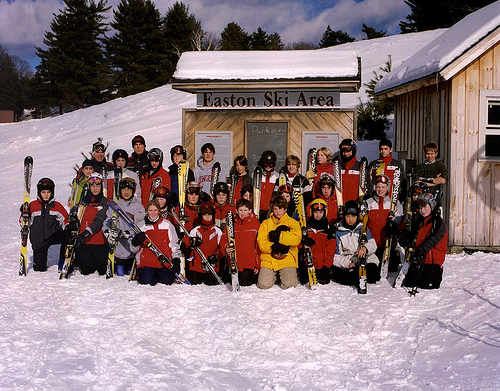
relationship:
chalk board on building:
[244, 120, 294, 160] [154, 47, 369, 179]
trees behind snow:
[28, 0, 173, 112] [48, 109, 135, 136]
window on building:
[483, 98, 498, 160] [373, 4, 495, 250]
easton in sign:
[202, 90, 256, 107] [198, 91, 341, 108]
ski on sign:
[259, 90, 289, 118] [193, 87, 310, 112]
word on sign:
[293, 90, 333, 108] [196, 91, 340, 110]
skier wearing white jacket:
[331, 200, 388, 292] [319, 202, 388, 290]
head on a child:
[421, 131, 439, 158] [420, 137, 440, 187]